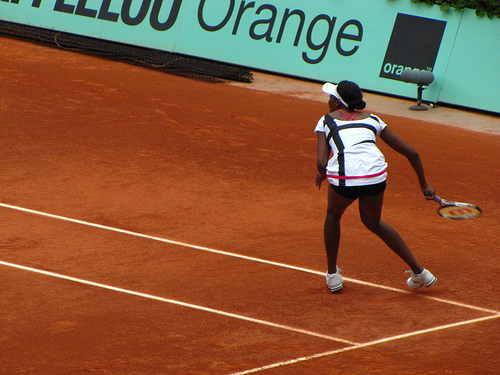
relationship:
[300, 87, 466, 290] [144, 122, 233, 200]
woman on court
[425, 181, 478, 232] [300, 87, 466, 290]
racket on woman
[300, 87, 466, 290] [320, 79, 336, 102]
woman wearing hat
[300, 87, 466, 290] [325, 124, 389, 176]
woman wearing outfit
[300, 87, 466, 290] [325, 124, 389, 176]
woman with outfit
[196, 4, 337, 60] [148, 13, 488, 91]
letter on sign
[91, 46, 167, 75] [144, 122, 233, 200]
tarp on court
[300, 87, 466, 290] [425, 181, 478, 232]
woman holding racket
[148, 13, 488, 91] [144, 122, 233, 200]
sign near court